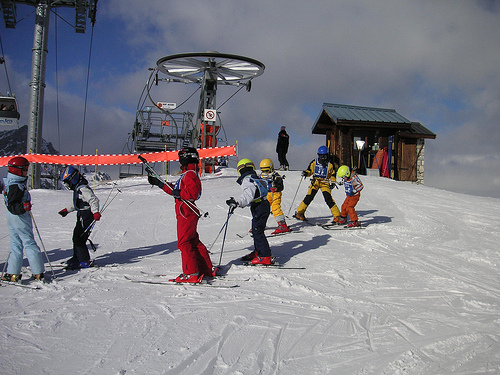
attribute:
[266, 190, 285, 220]
snowpants — yellow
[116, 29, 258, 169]
ski lift — white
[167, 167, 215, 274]
red snowsuit — red 